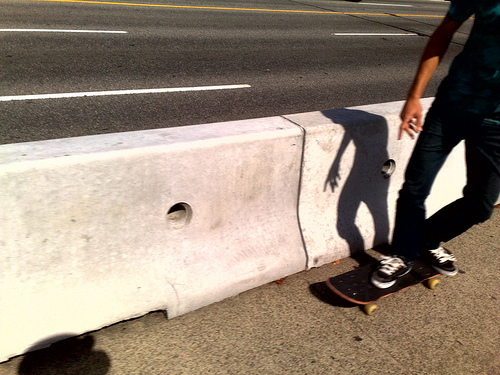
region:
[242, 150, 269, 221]
part of a wall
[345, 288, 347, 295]
part of a board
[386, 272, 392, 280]
part of a shoe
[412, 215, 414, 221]
part of a jeans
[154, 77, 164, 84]
part of a road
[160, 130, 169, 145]
edge of a wall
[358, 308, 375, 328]
part of a wheel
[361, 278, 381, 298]
tip of a board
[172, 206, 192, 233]
part of a hole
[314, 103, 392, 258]
the shadow of a guy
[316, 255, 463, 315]
a black skateboard with dingy wheels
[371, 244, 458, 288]
a pair of black skater shoes with white laces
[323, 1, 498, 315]
a guy skating on a skateboard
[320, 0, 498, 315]
a guy standing on a skateboard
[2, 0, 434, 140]
part of a black road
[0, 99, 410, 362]
part of a concrete medium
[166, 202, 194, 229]
a whole in concrete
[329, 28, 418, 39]
a white line divider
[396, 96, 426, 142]
a guys hand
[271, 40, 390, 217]
man's shadow on concrete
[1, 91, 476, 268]
concrete divider on highway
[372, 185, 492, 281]
man's feet on skateboard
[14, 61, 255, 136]
white lines on black pavement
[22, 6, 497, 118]
black paved highway on left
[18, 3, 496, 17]
yellow lines on paved highway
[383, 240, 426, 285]
white laces on black shoes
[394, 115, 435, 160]
finger pointed out on hand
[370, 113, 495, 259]
tight black jeans on skater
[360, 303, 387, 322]
yellow wheels on skater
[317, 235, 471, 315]
person riding a skateboard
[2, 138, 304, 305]
concrete barrier dividing road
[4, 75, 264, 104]
stripe painted on a road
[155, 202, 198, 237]
hole in the concrete barrier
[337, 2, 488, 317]
person riding on a skateboard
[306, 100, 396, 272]
person's shadow riding a skateboard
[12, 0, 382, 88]
black paved asphalt roadway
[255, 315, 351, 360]
concrete sidewalk with flecks of stone in it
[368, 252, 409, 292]
black and white sneakers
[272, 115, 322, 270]
crack in concrete wall divider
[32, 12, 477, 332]
a skateboarder near a street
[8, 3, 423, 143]
a three lane street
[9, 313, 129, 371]
a shadow in the picture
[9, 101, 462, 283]
a divider near the street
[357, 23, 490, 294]
a skateboarder near the divider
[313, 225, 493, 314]
the skateboard is black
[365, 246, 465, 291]
the skater has on black and white shoes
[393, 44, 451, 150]
the skater's arm in the shot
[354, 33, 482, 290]
the skater has on black pants